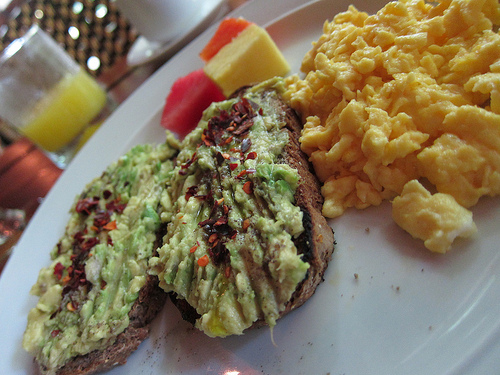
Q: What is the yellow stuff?
A: Macaroni and cheese.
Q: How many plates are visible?
A: One.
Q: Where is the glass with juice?
A: Beyond the plate.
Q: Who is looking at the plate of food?
A: The photographer.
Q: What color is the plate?
A: White.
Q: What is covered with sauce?
A: Meat.